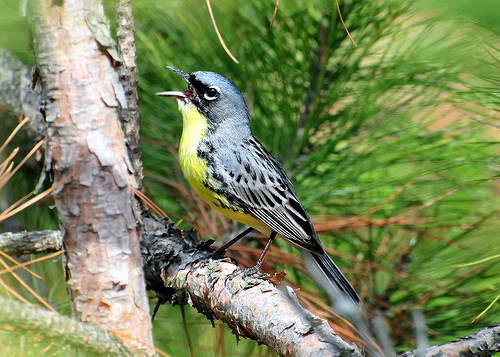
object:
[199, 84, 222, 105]
eye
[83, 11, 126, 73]
bark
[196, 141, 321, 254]
wing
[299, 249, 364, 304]
tail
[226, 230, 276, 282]
legs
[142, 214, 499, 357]
branch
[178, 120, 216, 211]
chest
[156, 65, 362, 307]
bird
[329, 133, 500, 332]
grass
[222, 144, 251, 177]
blue feathers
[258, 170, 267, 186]
black markings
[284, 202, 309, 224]
feathers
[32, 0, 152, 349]
trunk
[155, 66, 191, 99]
beak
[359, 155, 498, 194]
palm fronds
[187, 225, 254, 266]
legs